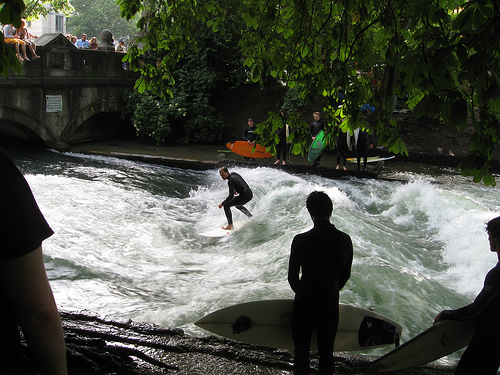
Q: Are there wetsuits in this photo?
A: Yes, there is a wetsuit.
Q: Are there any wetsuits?
A: Yes, there is a wetsuit.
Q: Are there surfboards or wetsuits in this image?
A: Yes, there is a wetsuit.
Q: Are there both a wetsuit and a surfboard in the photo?
A: Yes, there are both a wetsuit and a surfboard.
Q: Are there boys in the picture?
A: No, there are no boys.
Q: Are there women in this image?
A: No, there are no women.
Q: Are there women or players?
A: No, there are no women or players.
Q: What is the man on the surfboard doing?
A: The man is surfing.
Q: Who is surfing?
A: The man is surfing.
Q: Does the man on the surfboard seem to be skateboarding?
A: No, the man is surfing.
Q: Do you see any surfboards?
A: Yes, there is a surfboard.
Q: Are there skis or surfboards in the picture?
A: Yes, there is a surfboard.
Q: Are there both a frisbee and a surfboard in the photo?
A: No, there is a surfboard but no frisbees.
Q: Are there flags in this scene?
A: No, there are no flags.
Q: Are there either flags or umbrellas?
A: No, there are no flags or umbrellas.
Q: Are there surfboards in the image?
A: Yes, there is a surfboard.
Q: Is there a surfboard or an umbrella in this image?
A: Yes, there is a surfboard.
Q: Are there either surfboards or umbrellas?
A: Yes, there is a surfboard.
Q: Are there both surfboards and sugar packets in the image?
A: No, there is a surfboard but no sugar packets.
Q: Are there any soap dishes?
A: No, there are no soap dishes.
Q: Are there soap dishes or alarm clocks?
A: No, there are no soap dishes or alarm clocks.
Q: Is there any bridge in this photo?
A: Yes, there is a bridge.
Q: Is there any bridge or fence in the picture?
A: Yes, there is a bridge.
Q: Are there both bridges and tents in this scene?
A: No, there is a bridge but no tents.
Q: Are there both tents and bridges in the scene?
A: No, there is a bridge but no tents.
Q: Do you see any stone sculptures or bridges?
A: Yes, there is a stone bridge.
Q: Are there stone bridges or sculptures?
A: Yes, there is a stone bridge.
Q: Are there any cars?
A: No, there are no cars.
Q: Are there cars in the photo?
A: No, there are no cars.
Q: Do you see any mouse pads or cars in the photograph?
A: No, there are no cars or mouse pads.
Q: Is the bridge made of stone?
A: Yes, the bridge is made of stone.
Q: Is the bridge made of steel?
A: No, the bridge is made of stone.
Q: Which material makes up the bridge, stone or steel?
A: The bridge is made of stone.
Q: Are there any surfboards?
A: Yes, there is a surfboard.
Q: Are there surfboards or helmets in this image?
A: Yes, there is a surfboard.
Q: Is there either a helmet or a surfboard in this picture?
A: Yes, there is a surfboard.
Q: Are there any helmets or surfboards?
A: Yes, there is a surfboard.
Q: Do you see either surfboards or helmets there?
A: Yes, there is a surfboard.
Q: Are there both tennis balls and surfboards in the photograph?
A: No, there is a surfboard but no tennis balls.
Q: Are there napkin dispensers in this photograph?
A: No, there are no napkin dispensers.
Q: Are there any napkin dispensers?
A: No, there are no napkin dispensers.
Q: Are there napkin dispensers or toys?
A: No, there are no napkin dispensers or toys.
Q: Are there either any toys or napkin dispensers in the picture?
A: No, there are no napkin dispensers or toys.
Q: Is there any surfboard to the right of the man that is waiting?
A: Yes, there is a surfboard to the right of the man.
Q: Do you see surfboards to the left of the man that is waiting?
A: No, the surfboard is to the right of the man.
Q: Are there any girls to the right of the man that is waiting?
A: No, there is a surfboard to the right of the man.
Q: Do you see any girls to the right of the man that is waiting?
A: No, there is a surfboard to the right of the man.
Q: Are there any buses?
A: No, there are no buses.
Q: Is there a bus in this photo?
A: No, there are no buses.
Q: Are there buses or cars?
A: No, there are no buses or cars.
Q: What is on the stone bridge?
A: The sign is on the bridge.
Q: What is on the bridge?
A: The sign is on the bridge.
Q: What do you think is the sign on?
A: The sign is on the bridge.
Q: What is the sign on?
A: The sign is on the bridge.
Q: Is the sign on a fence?
A: No, the sign is on a bridge.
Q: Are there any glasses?
A: No, there are no glasses.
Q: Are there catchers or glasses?
A: No, there are no glasses or catchers.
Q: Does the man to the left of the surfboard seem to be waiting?
A: Yes, the man is waiting.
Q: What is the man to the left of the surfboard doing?
A: The man is waiting.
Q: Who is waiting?
A: The man is waiting.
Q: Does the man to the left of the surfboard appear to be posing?
A: No, the man is waiting.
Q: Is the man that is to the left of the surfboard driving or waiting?
A: The man is waiting.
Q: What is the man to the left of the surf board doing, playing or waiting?
A: The man is waiting.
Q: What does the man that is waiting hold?
A: The man holds the surfboard.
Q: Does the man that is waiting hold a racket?
A: No, the man holds the surfboard.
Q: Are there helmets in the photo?
A: No, there are no helmets.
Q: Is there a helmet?
A: No, there are no helmets.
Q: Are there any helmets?
A: No, there are no helmets.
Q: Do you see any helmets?
A: No, there are no helmets.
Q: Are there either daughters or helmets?
A: No, there are no helmets or daughters.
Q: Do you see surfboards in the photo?
A: Yes, there is a surfboard.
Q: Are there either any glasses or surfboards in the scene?
A: Yes, there is a surfboard.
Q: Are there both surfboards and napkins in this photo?
A: No, there is a surfboard but no napkins.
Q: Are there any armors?
A: No, there are no armors.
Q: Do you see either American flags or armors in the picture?
A: No, there are no armors or American flags.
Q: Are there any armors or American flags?
A: No, there are no armors or American flags.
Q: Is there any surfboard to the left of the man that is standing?
A: Yes, there is a surfboard to the left of the man.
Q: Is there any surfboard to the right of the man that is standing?
A: No, the surfboard is to the left of the man.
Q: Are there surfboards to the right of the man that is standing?
A: No, the surfboard is to the left of the man.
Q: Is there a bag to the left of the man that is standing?
A: No, there is a surfboard to the left of the man.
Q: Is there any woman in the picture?
A: No, there are no women.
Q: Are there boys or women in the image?
A: No, there are no women or boys.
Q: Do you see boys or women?
A: No, there are no women or boys.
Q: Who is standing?
A: The man is standing.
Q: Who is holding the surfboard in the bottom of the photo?
A: The man is holding the surfboard.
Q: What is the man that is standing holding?
A: The man is holding the surfboard.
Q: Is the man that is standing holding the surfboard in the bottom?
A: Yes, the man is holding the surfboard.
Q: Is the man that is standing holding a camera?
A: No, the man is holding the surfboard.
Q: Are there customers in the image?
A: No, there are no customers.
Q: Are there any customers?
A: No, there are no customers.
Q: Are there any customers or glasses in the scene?
A: No, there are no customers or glasses.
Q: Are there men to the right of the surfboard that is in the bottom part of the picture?
A: Yes, there is a man to the right of the surfboard.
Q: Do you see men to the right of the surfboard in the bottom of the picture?
A: Yes, there is a man to the right of the surfboard.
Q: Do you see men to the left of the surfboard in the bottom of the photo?
A: No, the man is to the right of the surfboard.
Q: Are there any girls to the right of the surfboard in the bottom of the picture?
A: No, there is a man to the right of the surfboard.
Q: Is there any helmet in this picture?
A: No, there are no helmets.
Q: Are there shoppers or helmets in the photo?
A: No, there are no helmets or shoppers.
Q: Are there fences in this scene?
A: No, there are no fences.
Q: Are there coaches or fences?
A: No, there are no fences or coaches.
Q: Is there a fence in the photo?
A: No, there are no fences.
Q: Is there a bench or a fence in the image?
A: No, there are no fences or benches.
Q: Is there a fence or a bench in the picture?
A: No, there are no fences or benches.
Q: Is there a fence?
A: No, there are no fences.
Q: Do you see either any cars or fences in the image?
A: No, there are no fences or cars.